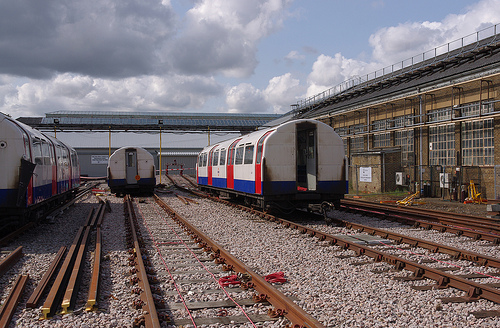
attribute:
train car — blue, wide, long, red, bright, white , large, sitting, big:
[196, 116, 352, 214]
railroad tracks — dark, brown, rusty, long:
[312, 212, 498, 318]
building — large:
[276, 27, 499, 202]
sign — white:
[356, 162, 372, 184]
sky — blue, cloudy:
[2, 2, 499, 113]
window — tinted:
[243, 144, 254, 165]